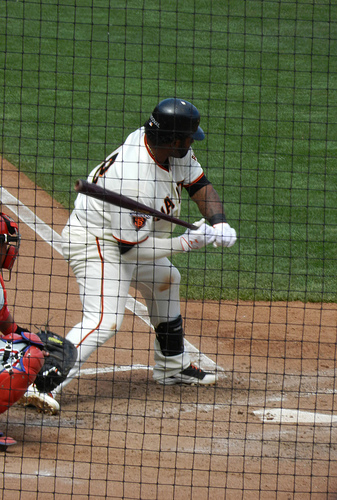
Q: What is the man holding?
A: A bat.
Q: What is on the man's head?
A: Helmet.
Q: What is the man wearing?
A: A uniform.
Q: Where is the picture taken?
A: A baseball field.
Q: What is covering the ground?
A: Grass.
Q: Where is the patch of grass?
A: In front of player.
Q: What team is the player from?
A: Giants.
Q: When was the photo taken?
A: Daytime.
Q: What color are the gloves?
A: White.